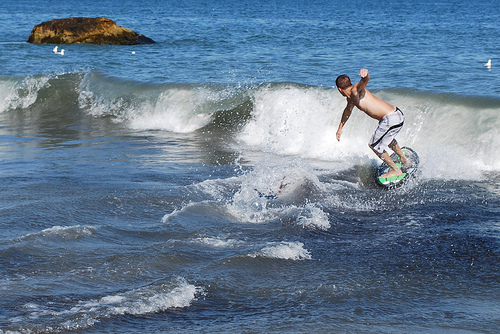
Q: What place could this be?
A: It is an ocean.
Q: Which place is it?
A: It is an ocean.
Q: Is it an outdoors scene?
A: Yes, it is outdoors.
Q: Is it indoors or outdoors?
A: It is outdoors.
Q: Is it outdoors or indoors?
A: It is outdoors.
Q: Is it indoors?
A: No, it is outdoors.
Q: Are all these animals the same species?
A: No, there are both sea gulls and birds.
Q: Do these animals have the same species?
A: No, there are both sea gulls and birds.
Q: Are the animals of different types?
A: Yes, they are seagulls and birds.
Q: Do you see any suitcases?
A: No, there are no suitcases.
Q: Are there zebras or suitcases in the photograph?
A: No, there are no suitcases or zebras.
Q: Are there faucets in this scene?
A: No, there are no faucets.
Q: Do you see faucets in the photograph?
A: No, there are no faucets.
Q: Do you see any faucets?
A: No, there are no faucets.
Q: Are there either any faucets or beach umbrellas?
A: No, there are no faucets or beach umbrellas.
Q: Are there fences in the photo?
A: No, there are no fences.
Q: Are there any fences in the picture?
A: No, there are no fences.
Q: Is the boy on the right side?
A: Yes, the boy is on the right of the image.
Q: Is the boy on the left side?
A: No, the boy is on the right of the image.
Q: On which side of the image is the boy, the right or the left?
A: The boy is on the right of the image.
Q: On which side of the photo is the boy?
A: The boy is on the right of the image.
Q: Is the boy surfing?
A: Yes, the boy is surfing.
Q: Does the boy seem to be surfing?
A: Yes, the boy is surfing.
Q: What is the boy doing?
A: The boy is surfing.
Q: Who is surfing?
A: The boy is surfing.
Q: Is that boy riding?
A: No, the boy is surfing.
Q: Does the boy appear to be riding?
A: No, the boy is surfing.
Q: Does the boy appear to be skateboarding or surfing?
A: The boy is surfing.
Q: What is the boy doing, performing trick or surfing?
A: The boy is surfing.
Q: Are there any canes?
A: No, there are no canes.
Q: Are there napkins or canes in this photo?
A: No, there are no canes or napkins.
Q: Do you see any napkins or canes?
A: No, there are no canes or napkins.